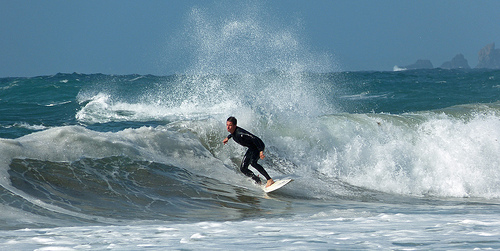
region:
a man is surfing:
[106, 60, 301, 249]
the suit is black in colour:
[210, 130, 283, 185]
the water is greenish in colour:
[28, 46, 63, 143]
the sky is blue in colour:
[13, 10, 108, 51]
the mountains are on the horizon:
[379, 38, 478, 82]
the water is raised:
[123, 20, 301, 111]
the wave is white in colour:
[298, 96, 460, 189]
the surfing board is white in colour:
[236, 165, 306, 202]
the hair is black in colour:
[223, 109, 238, 121]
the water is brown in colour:
[41, 147, 178, 242]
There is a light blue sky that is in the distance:
[411, 13, 442, 78]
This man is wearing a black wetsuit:
[223, 131, 283, 181]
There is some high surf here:
[409, 126, 455, 203]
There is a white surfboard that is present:
[250, 174, 287, 196]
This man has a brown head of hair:
[226, 115, 238, 132]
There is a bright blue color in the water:
[28, 75, 49, 111]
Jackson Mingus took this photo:
[132, 13, 377, 220]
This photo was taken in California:
[143, 20, 377, 220]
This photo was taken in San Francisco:
[156, 19, 283, 230]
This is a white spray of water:
[199, 16, 271, 89]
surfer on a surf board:
[212, 103, 301, 204]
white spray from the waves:
[215, 21, 320, 96]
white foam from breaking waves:
[309, 76, 494, 227]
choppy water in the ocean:
[28, 68, 96, 135]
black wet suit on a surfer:
[225, 123, 270, 192]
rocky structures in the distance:
[380, 28, 497, 83]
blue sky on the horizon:
[59, 20, 162, 79]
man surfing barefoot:
[216, 114, 304, 205]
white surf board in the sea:
[258, 172, 296, 203]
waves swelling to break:
[25, 123, 176, 235]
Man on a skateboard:
[217, 109, 293, 206]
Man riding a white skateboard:
[240, 162, 298, 201]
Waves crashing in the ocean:
[356, 100, 486, 192]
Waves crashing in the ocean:
[56, 123, 141, 206]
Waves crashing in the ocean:
[78, 65, 156, 96]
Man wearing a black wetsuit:
[233, 130, 260, 181]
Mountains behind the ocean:
[393, 46, 472, 73]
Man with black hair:
[218, 119, 243, 130]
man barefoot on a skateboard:
[256, 171, 277, 190]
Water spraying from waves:
[204, 43, 333, 130]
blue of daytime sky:
[3, 0, 498, 72]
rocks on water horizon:
[402, 42, 497, 72]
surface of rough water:
[0, 68, 494, 118]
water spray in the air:
[108, 9, 337, 130]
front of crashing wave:
[3, 102, 498, 221]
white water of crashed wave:
[346, 113, 497, 193]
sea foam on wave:
[14, 161, 221, 221]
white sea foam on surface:
[18, 211, 498, 249]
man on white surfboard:
[223, 115, 290, 190]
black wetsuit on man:
[226, 126, 270, 183]